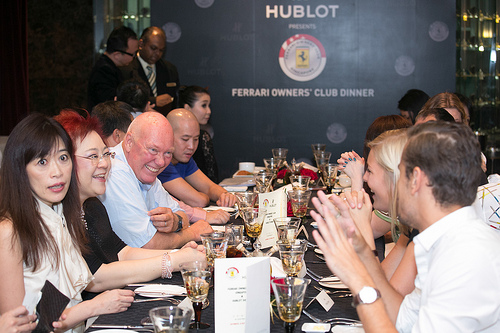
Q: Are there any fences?
A: No, there are no fences.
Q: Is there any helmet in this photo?
A: No, there are no helmets.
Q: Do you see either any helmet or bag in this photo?
A: No, there are no helmets or bags.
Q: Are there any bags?
A: No, there are no bags.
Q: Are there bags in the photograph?
A: No, there are no bags.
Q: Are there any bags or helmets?
A: No, there are no bags or helmets.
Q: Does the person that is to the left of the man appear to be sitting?
A: Yes, the person is sitting.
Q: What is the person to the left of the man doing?
A: The person is sitting.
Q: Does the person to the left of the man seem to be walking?
A: No, the person is sitting.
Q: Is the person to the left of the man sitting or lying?
A: The person is sitting.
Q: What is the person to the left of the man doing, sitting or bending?
A: The person is sitting.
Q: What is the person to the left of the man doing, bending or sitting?
A: The person is sitting.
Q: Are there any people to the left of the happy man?
A: Yes, there is a person to the left of the man.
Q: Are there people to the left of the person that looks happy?
A: Yes, there is a person to the left of the man.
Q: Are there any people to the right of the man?
A: No, the person is to the left of the man.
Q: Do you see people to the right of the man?
A: No, the person is to the left of the man.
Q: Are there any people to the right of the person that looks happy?
A: No, the person is to the left of the man.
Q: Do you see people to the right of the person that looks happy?
A: No, the person is to the left of the man.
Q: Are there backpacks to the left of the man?
A: No, there is a person to the left of the man.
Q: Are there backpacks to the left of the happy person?
A: No, there is a person to the left of the man.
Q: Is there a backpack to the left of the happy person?
A: No, there is a person to the left of the man.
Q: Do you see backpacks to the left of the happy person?
A: No, there is a person to the left of the man.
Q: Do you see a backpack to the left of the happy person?
A: No, there is a person to the left of the man.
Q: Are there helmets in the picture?
A: No, there are no helmets.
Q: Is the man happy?
A: Yes, the man is happy.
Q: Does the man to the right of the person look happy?
A: Yes, the man is happy.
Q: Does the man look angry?
A: No, the man is happy.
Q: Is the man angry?
A: No, the man is happy.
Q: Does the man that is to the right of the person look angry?
A: No, the man is happy.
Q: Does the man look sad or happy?
A: The man is happy.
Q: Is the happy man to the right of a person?
A: Yes, the man is to the right of a person.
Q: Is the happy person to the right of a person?
A: Yes, the man is to the right of a person.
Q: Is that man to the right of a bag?
A: No, the man is to the right of a person.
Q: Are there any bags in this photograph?
A: No, there are no bags.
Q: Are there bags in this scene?
A: No, there are no bags.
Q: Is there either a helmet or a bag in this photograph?
A: No, there are no bags or helmets.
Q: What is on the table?
A: The menu is on the table.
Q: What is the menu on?
A: The menu is on the table.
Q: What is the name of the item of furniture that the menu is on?
A: The piece of furniture is a table.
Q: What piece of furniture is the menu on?
A: The menu is on the table.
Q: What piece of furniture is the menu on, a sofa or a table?
A: The menu is on a table.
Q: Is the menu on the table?
A: Yes, the menu is on the table.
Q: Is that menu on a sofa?
A: No, the menu is on the table.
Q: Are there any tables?
A: Yes, there is a table.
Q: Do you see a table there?
A: Yes, there is a table.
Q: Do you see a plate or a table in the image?
A: Yes, there is a table.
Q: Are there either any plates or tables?
A: Yes, there is a table.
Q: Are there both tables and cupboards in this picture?
A: No, there is a table but no cupboards.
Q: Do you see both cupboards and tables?
A: No, there is a table but no cupboards.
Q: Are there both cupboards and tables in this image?
A: No, there is a table but no cupboards.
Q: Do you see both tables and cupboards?
A: No, there is a table but no cupboards.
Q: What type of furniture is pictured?
A: The furniture is a table.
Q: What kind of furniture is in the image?
A: The furniture is a table.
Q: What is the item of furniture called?
A: The piece of furniture is a table.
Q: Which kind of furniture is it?
A: The piece of furniture is a table.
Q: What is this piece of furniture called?
A: This is a table.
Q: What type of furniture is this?
A: This is a table.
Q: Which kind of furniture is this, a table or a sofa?
A: This is a table.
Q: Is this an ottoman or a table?
A: This is a table.